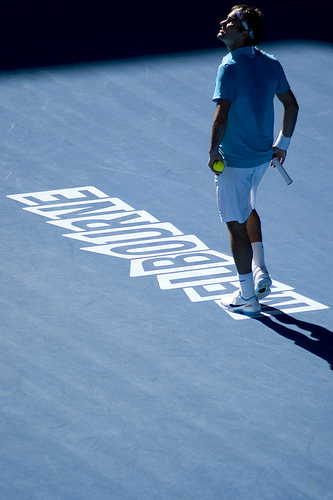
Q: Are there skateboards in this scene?
A: No, there are no skateboards.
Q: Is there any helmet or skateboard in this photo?
A: No, there are no skateboards or helmets.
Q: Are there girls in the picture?
A: No, there are no girls.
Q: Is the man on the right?
A: Yes, the man is on the right of the image.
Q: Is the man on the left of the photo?
A: No, the man is on the right of the image.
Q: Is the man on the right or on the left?
A: The man is on the right of the image.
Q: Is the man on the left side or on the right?
A: The man is on the right of the image.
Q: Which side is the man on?
A: The man is on the right of the image.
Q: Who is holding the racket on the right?
A: The man is holding the racket.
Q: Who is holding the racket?
A: The man is holding the racket.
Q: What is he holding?
A: The man is holding the tennis racket.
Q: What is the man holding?
A: The man is holding the tennis racket.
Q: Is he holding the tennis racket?
A: Yes, the man is holding the tennis racket.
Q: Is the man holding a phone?
A: No, the man is holding the tennis racket.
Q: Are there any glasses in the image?
A: No, there are no glasses.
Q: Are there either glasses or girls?
A: No, there are no glasses or girls.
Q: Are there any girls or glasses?
A: No, there are no glasses or girls.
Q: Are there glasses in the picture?
A: No, there are no glasses.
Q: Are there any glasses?
A: No, there are no glasses.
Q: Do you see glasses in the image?
A: No, there are no glasses.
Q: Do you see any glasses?
A: No, there are no glasses.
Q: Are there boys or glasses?
A: No, there are no glasses or boys.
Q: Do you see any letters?
A: Yes, there are letters.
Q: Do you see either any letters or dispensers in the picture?
A: Yes, there are letters.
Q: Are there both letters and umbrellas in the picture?
A: No, there are letters but no umbrellas.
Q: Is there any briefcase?
A: No, there are no briefcases.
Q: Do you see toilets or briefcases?
A: No, there are no briefcases or toilets.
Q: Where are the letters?
A: The letters are on the floor.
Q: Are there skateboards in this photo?
A: No, there are no skateboards.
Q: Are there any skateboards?
A: No, there are no skateboards.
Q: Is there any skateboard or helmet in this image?
A: No, there are no skateboards or helmets.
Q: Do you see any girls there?
A: No, there are no girls.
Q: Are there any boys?
A: No, there are no boys.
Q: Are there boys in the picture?
A: No, there are no boys.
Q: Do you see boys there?
A: No, there are no boys.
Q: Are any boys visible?
A: No, there are no boys.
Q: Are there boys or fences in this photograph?
A: No, there are no boys or fences.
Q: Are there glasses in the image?
A: No, there are no glasses.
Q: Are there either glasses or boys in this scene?
A: No, there are no glasses or boys.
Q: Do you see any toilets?
A: No, there are no toilets.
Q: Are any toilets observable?
A: No, there are no toilets.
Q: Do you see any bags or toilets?
A: No, there are no toilets or bags.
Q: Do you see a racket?
A: Yes, there is a racket.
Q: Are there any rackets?
A: Yes, there is a racket.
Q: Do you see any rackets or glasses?
A: Yes, there is a racket.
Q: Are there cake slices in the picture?
A: No, there are no cake slices.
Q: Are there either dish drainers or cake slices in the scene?
A: No, there are no cake slices or dish drainers.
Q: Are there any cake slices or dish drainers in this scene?
A: No, there are no cake slices or dish drainers.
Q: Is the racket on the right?
A: Yes, the racket is on the right of the image.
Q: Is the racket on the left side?
A: No, the racket is on the right of the image.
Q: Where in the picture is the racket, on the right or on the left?
A: The racket is on the right of the image.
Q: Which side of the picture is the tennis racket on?
A: The tennis racket is on the right of the image.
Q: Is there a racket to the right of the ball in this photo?
A: Yes, there is a racket to the right of the ball.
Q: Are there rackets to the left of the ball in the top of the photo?
A: No, the racket is to the right of the ball.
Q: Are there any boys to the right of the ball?
A: No, there is a racket to the right of the ball.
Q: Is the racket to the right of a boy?
A: No, the racket is to the right of the ball.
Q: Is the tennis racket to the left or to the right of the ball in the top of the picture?
A: The tennis racket is to the right of the ball.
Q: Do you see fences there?
A: No, there are no fences.